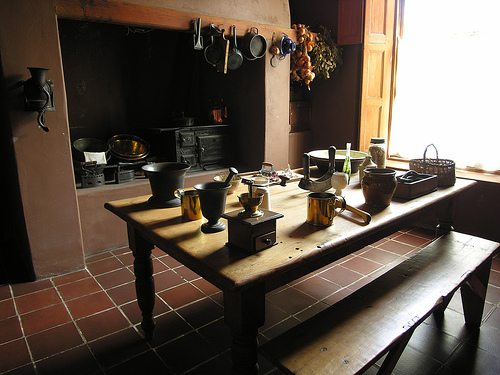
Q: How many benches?
A: One.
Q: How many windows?
A: One.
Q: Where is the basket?
A: On the table.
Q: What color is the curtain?
A: White.